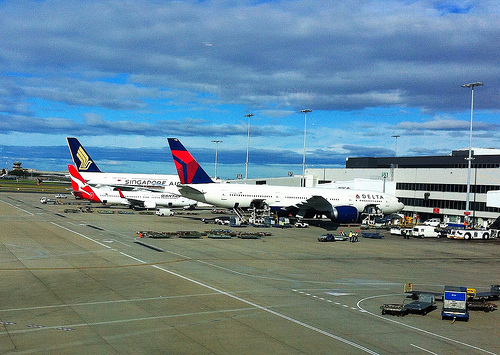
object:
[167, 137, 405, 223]
plane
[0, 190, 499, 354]
runway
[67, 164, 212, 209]
plane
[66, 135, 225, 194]
plane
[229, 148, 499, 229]
building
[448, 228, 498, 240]
cars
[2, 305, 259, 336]
line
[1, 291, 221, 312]
line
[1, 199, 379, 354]
line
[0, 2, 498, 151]
sky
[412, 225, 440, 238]
van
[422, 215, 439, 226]
van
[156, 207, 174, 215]
van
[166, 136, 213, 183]
tail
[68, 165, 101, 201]
tail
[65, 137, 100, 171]
tail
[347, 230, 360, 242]
people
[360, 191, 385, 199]
branding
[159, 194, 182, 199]
branding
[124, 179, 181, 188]
branding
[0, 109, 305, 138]
clouds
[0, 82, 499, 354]
airport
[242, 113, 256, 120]
lights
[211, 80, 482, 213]
line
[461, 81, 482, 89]
light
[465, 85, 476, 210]
pole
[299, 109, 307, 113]
light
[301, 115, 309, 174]
pole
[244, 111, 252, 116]
light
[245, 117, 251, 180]
pole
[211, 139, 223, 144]
light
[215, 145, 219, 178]
pole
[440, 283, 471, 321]
baggage cart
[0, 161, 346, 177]
water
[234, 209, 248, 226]
ramp